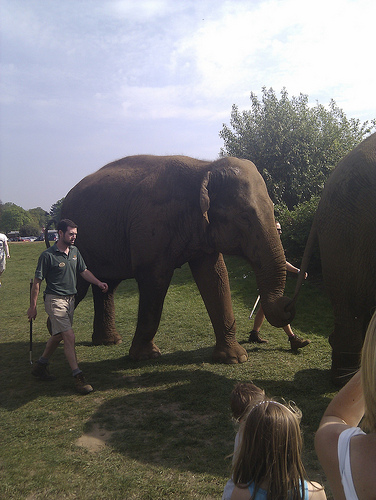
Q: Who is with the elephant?
A: The trainers.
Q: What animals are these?
A: Elephants.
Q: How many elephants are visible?
A: Two.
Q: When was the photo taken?
A: Daytime.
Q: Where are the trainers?
A: Near the elephants.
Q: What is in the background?
A: Trees.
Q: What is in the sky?
A: Clouds.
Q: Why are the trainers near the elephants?
A: To guide them.